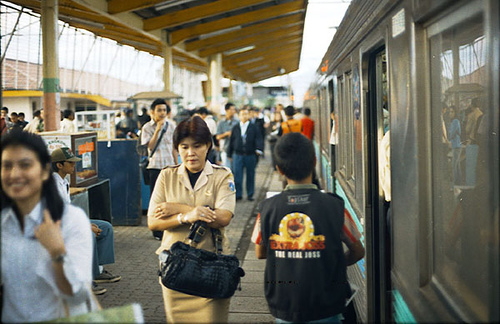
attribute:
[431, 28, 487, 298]
window — reflecting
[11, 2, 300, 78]
awning — wooden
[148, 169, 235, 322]
suit — beige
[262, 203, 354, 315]
vest — black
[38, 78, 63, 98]
stripe — green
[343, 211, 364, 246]
sleeves — striped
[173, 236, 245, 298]
handbag — black, held, carried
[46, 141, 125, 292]
boy — sitting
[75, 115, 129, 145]
railing — white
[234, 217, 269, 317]
sidewalk — gray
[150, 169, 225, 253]
shirt — brown, ta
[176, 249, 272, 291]
bag — black, carried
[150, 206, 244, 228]
arms — crossed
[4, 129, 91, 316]
woman — smiling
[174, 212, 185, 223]
watch — worn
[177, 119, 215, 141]
hair — brown, dark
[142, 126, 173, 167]
shoulderbag — worn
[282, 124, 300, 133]
shirt — orange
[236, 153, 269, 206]
pats — blue